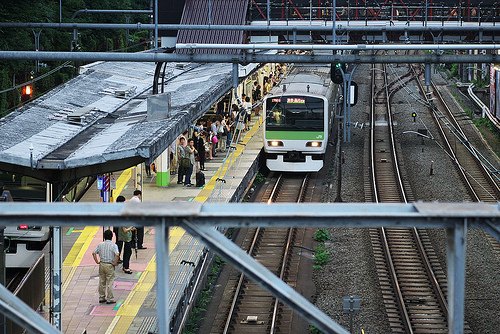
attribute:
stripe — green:
[265, 130, 323, 141]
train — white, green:
[263, 49, 336, 172]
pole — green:
[156, 149, 169, 187]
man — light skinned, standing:
[93, 229, 121, 304]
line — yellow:
[60, 114, 133, 334]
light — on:
[267, 139, 282, 149]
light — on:
[307, 141, 321, 148]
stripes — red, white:
[103, 171, 111, 191]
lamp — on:
[23, 79, 33, 98]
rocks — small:
[316, 57, 374, 333]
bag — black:
[195, 169, 206, 187]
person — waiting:
[178, 137, 187, 184]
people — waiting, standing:
[179, 105, 240, 188]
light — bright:
[22, 82, 38, 98]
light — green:
[335, 58, 342, 73]